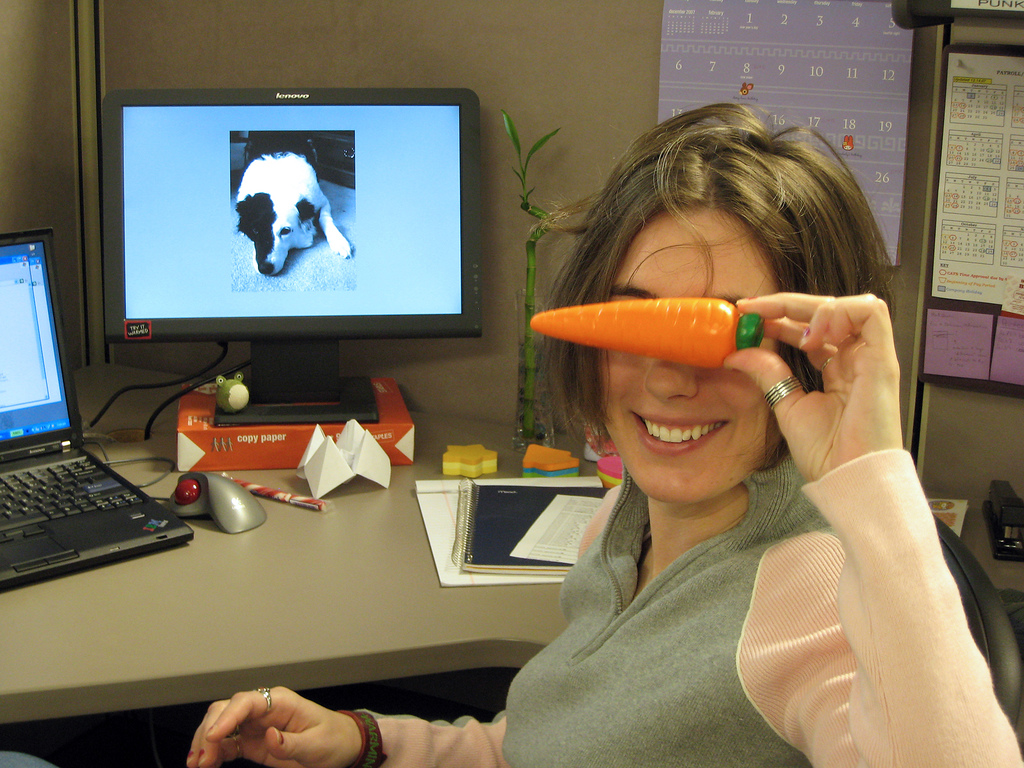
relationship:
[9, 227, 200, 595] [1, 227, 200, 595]
side of a laptop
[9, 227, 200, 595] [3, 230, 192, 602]
side of a computer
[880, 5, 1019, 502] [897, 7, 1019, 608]
side of a wall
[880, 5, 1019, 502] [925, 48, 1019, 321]
side of a calendar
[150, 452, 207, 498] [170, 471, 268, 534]
button attached to computer mouse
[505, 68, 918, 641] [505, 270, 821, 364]
woman holding carrot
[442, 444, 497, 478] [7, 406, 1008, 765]
note pad on desk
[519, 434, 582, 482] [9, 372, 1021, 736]
paper pad on desk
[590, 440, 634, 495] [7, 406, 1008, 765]
paper pad on desk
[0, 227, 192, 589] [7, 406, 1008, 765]
computer on desk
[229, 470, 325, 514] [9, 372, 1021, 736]
pen laying on desk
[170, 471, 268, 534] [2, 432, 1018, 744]
computer mouse on desk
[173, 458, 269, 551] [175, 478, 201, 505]
computer mouse with a button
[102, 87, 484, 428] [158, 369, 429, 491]
computer sitting on a package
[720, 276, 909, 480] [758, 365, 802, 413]
hand with ring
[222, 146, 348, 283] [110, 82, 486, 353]
dog on a computer screen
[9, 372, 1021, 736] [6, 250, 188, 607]
desk with a laptop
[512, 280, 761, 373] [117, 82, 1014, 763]
carrot held in front of eyes of woman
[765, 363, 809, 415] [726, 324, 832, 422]
ring around thumb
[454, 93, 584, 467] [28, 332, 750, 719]
plant on desk